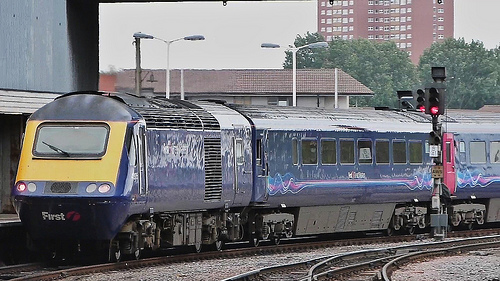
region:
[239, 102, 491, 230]
the train is blue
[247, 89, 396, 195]
the train is blue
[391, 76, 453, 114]
the light is red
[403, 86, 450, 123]
the light is red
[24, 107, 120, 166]
window on passenger train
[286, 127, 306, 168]
window on passenger train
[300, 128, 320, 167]
window on passenger train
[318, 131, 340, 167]
window on passenger train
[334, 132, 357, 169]
window on passenger train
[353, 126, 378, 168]
window on passenger train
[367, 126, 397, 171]
window on passenger train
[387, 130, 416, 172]
window on passenger train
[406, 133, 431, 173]
window on passenger train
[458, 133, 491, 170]
window on passenger train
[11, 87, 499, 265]
A blue train on tracks.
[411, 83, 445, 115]
Two traffic lights on red.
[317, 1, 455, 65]
A red brick building.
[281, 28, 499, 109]
Trees behind the train.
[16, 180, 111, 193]
Lights on a train.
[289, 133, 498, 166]
Windows on a train.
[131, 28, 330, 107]
Lights on some poles.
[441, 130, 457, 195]
Red door on a train.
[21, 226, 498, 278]
Tracks on the ground.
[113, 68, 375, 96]
A buildings brown roof.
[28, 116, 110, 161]
Windshield on train, with a windshield wiper.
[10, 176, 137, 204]
Headlights on the train car.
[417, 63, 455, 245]
Stop light on the tracks, with a red light showing.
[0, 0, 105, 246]
Blue green building in the foreground.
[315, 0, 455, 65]
Tall red building far off in the distance.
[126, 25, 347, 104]
Two street lights, with white poles.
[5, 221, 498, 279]
Two sets of train tracks running parallel.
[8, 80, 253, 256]
Blue and yellow train car labeled "First".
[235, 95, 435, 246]
Blue train car with a stripe of blue, white, pink, and green graffiti.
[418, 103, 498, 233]
Blue train car with a stripe of blue, white, pink, and green graffiti.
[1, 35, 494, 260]
A train is going through a city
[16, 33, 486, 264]
A train is traveling very slowly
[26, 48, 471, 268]
A train is on the railroad tracks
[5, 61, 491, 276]
A locomotive is pulling some cars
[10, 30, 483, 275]
A train is coming to a station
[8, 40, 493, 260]
A train is passing the building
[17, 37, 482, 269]
The train is obeying the law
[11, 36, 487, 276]
The train is traveling in daytime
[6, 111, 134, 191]
yellow part of train engine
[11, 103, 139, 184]
yellow part of train engine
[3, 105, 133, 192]
yellow part of train engine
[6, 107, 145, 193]
yellow part of train engine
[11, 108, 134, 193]
yellow part of train engine